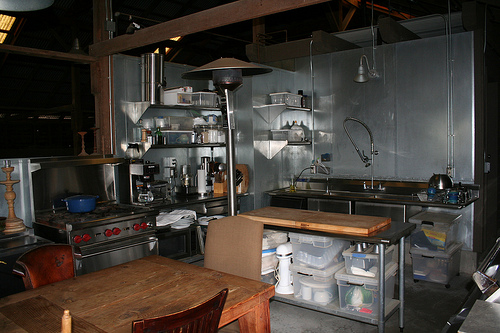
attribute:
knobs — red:
[71, 221, 163, 245]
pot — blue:
[58, 188, 107, 216]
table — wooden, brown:
[80, 266, 274, 313]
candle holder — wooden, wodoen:
[1, 157, 26, 234]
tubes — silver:
[444, 58, 459, 172]